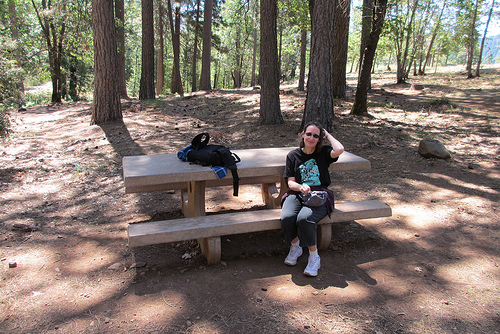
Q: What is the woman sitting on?
A: Bench.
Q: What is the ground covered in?
A: Dirt.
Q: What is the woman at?
A: Pinic table.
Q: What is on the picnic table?
A: A bag.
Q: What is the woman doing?
A: Sitting.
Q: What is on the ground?
A: Shadow.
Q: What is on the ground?
A: Sunlight.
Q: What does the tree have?
A: Trunks.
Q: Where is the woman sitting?
A: On a bench.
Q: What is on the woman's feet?
A: Sneakers.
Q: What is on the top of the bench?
A: A black bag.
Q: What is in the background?
A: Trees.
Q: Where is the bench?
A: In dirt.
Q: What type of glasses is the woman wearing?
A: Sunglasses.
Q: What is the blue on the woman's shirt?
A: A design.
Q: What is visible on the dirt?
A: Shadows of the trees.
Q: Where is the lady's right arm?
A: Touching her head.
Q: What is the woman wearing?
A: Shoes.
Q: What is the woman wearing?
A: Jeans.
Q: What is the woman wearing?
A: Shirt.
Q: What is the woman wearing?
A: Pant.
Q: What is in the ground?
A: Bench.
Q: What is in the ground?
A: Rocks.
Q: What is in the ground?
A: Trees.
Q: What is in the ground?
A: Plants.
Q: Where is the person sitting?
A: At a picnic table.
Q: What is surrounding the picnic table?
A: Trees.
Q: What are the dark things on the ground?
A: Shadows.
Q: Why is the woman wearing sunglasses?
A: It's sunny out.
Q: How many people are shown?
A: One.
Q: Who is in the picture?
A: A woman.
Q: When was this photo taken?
A: During the daytime.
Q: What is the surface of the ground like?
A: Gravel path.